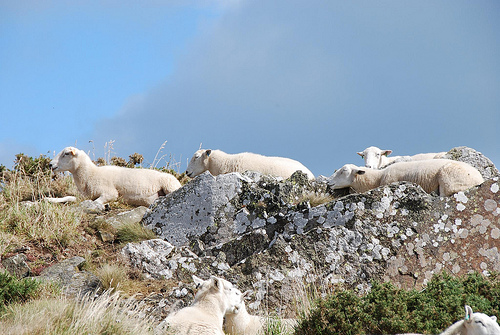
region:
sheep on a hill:
[42, 136, 494, 213]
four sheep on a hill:
[42, 140, 487, 220]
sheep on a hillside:
[45, 130, 497, 334]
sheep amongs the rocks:
[37, 128, 499, 332]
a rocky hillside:
[155, 150, 475, 315]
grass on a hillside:
[4, 142, 60, 249]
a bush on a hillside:
[300, 263, 480, 334]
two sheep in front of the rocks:
[155, 272, 273, 334]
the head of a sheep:
[183, 146, 215, 180]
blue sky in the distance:
[21, 17, 169, 96]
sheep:
[52, 137, 189, 209]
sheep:
[174, 128, 306, 207]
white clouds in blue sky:
[35, 36, 129, 89]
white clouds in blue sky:
[404, 72, 442, 97]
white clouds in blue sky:
[350, 29, 400, 97]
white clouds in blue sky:
[236, 55, 296, 82]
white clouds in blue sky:
[197, 89, 287, 134]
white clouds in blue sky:
[155, 62, 249, 111]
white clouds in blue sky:
[103, 96, 158, 121]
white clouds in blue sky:
[46, 47, 106, 99]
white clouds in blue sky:
[317, 79, 415, 124]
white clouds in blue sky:
[110, 25, 163, 65]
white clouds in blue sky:
[226, 56, 267, 92]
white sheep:
[48, 145, 169, 216]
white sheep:
[173, 135, 313, 188]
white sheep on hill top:
[343, 122, 493, 206]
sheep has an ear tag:
[462, 305, 474, 320]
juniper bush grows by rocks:
[304, 269, 487, 334]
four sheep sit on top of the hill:
[31, 134, 498, 219]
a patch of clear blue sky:
[8, 10, 207, 124]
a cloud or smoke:
[91, 5, 498, 150]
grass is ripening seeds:
[70, 280, 156, 333]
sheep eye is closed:
[327, 161, 365, 188]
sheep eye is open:
[61, 148, 71, 160]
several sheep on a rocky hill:
[48, 105, 496, 255]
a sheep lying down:
[40, 131, 180, 226]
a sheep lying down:
[185, 131, 320, 213]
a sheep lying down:
[330, 160, 485, 200]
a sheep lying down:
[351, 141, 458, 167]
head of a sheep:
[428, 296, 499, 330]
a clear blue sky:
[4, 8, 488, 118]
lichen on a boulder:
[307, 208, 413, 266]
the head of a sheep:
[43, 139, 85, 181]